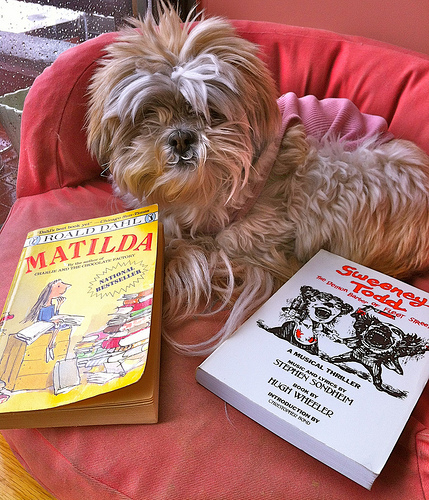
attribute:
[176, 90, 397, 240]
sweater — pink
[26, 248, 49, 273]
letter — red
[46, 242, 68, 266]
letter — red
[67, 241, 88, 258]
letter — red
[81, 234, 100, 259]
letter — red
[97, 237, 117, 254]
letter — red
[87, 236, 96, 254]
letter — red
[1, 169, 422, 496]
pillow — pink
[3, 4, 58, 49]
water drops — black and white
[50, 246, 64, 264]
letter — red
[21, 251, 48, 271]
letter — red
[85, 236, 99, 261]
letter — red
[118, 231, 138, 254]
letter — red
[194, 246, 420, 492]
book — yellow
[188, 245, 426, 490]
title — red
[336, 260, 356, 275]
letter — red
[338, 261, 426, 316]
writing — red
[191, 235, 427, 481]
book — black and white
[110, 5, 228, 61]
hair — black and white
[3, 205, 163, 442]
book — white, old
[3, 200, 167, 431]
cover — yellow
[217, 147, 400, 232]
fur — tan